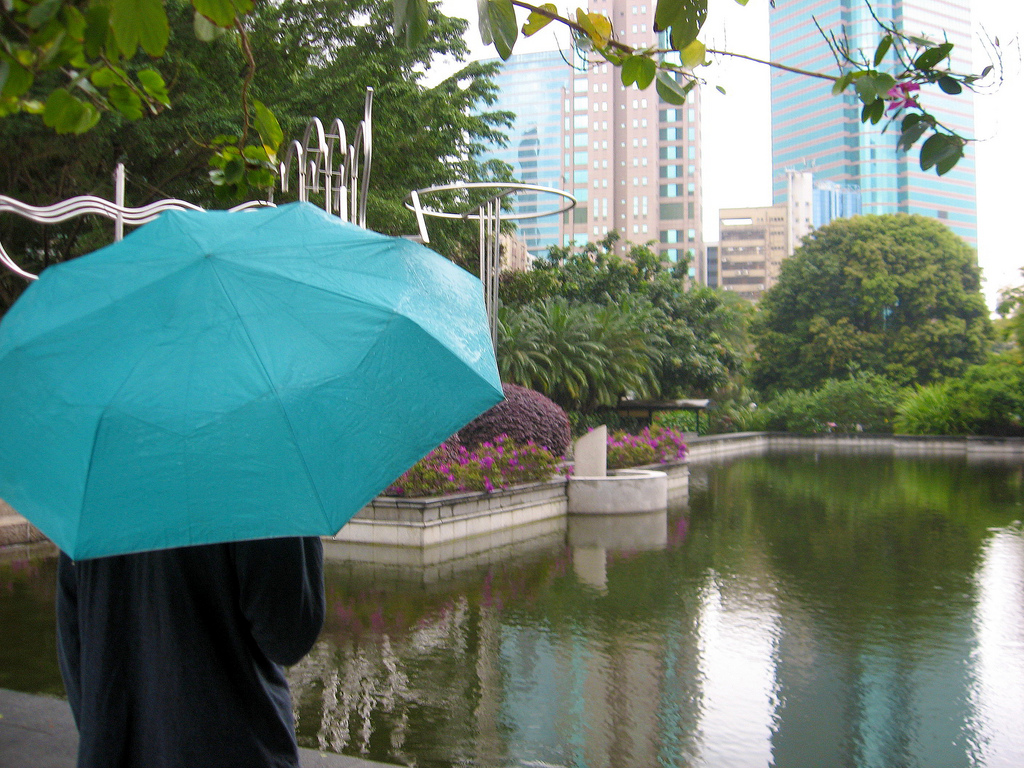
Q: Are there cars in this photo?
A: No, there are no cars.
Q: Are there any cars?
A: No, there are no cars.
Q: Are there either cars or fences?
A: No, there are no cars or fences.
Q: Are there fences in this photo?
A: No, there are no fences.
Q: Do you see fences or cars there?
A: No, there are no fences or cars.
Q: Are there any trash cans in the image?
A: No, there are no trash cans.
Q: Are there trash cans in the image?
A: No, there are no trash cans.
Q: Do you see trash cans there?
A: No, there are no trash cans.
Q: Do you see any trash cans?
A: No, there are no trash cans.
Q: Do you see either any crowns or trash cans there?
A: No, there are no trash cans or crowns.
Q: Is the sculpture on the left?
A: Yes, the sculpture is on the left of the image.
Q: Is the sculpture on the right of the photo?
A: No, the sculpture is on the left of the image.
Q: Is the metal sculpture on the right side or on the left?
A: The sculpture is on the left of the image.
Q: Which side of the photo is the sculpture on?
A: The sculpture is on the left of the image.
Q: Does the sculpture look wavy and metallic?
A: Yes, the sculpture is wavy and metallic.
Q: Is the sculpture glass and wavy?
A: No, the sculpture is wavy but metallic.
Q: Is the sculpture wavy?
A: Yes, the sculpture is wavy.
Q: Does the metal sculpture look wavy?
A: Yes, the sculpture is wavy.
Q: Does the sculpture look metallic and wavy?
A: Yes, the sculpture is metallic and wavy.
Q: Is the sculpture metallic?
A: Yes, the sculpture is metallic.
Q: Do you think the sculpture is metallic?
A: Yes, the sculpture is metallic.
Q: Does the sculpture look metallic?
A: Yes, the sculpture is metallic.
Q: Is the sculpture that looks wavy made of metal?
A: Yes, the sculpture is made of metal.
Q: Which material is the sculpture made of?
A: The sculpture is made of metal.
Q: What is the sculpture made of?
A: The sculpture is made of metal.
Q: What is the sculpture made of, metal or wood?
A: The sculpture is made of metal.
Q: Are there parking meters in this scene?
A: No, there are no parking meters.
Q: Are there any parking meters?
A: No, there are no parking meters.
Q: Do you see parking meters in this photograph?
A: No, there are no parking meters.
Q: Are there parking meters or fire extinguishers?
A: No, there are no parking meters or fire extinguishers.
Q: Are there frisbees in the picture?
A: No, there are no frisbees.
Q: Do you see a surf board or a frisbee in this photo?
A: No, there are no frisbees or surfboards.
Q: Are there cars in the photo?
A: No, there are no cars.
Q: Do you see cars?
A: No, there are no cars.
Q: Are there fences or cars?
A: No, there are no cars or fences.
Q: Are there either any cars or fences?
A: No, there are no cars or fences.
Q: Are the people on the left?
A: Yes, the people are on the left of the image.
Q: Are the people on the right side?
A: No, the people are on the left of the image.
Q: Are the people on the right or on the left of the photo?
A: The people are on the left of the image.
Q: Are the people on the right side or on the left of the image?
A: The people are on the left of the image.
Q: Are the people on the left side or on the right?
A: The people are on the left of the image.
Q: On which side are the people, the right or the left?
A: The people are on the left of the image.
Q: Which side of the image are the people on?
A: The people are on the left of the image.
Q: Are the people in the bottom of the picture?
A: Yes, the people are in the bottom of the image.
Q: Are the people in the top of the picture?
A: No, the people are in the bottom of the image.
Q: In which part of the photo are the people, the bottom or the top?
A: The people are in the bottom of the image.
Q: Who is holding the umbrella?
A: The people are holding the umbrella.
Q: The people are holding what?
A: The people are holding the umbrella.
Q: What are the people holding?
A: The people are holding the umbrella.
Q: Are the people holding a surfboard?
A: No, the people are holding the umbrella.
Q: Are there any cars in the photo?
A: No, there are no cars.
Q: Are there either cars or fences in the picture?
A: No, there are no cars or fences.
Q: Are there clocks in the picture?
A: No, there are no clocks.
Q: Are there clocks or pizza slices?
A: No, there are no clocks or pizza slices.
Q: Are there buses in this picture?
A: No, there are no buses.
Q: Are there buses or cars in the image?
A: No, there are no buses or cars.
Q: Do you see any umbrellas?
A: Yes, there is an umbrella.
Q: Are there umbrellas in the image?
A: Yes, there is an umbrella.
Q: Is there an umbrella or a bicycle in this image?
A: Yes, there is an umbrella.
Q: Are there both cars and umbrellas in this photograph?
A: No, there is an umbrella but no cars.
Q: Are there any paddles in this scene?
A: No, there are no paddles.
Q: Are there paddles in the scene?
A: No, there are no paddles.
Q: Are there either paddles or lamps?
A: No, there are no paddles or lamps.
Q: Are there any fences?
A: No, there are no fences.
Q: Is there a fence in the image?
A: No, there are no fences.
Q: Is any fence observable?
A: No, there are no fences.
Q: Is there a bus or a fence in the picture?
A: No, there are no fences or buses.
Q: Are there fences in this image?
A: No, there are no fences.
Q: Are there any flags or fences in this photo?
A: No, there are no fences or flags.